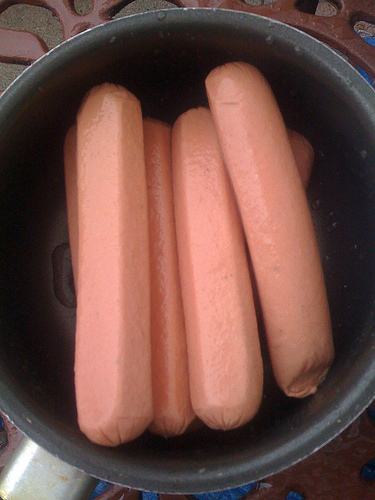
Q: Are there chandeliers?
A: No, there are no chandeliers.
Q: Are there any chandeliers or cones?
A: No, there are no chandeliers or cones.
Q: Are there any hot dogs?
A: Yes, there is a hot dog.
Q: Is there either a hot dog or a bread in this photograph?
A: Yes, there is a hot dog.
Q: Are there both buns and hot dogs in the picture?
A: No, there is a hot dog but no buns.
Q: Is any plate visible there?
A: No, there are no plates.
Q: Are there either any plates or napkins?
A: No, there are no plates or napkins.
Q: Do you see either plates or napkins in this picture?
A: No, there are no plates or napkins.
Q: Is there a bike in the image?
A: No, there are no bikes.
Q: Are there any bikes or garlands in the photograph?
A: No, there are no bikes or garlands.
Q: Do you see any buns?
A: No, there are no buns.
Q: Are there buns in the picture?
A: No, there are no buns.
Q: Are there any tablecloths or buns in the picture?
A: No, there are no buns or tablecloths.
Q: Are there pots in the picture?
A: Yes, there is a pot.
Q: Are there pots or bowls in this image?
A: Yes, there is a pot.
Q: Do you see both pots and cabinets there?
A: No, there is a pot but no cabinets.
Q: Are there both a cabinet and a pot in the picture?
A: No, there is a pot but no cabinets.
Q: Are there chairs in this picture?
A: No, there are no chairs.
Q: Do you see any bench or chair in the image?
A: No, there are no chairs or benches.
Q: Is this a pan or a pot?
A: This is a pot.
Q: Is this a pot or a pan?
A: This is a pot.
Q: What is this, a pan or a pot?
A: This is a pot.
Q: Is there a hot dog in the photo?
A: Yes, there is a hot dog.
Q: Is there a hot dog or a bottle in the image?
A: Yes, there is a hot dog.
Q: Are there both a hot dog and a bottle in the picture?
A: No, there is a hot dog but no bottles.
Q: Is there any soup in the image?
A: No, there is no soup.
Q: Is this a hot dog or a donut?
A: This is a hot dog.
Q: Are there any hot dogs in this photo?
A: Yes, there is a hot dog.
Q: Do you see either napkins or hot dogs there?
A: Yes, there is a hot dog.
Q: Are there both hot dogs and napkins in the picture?
A: No, there is a hot dog but no napkins.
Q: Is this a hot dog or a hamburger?
A: This is a hot dog.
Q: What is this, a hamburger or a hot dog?
A: This is a hot dog.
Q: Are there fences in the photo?
A: No, there are no fences.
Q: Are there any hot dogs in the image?
A: Yes, there is a hot dog.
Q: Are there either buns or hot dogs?
A: Yes, there is a hot dog.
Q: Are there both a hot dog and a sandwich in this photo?
A: No, there is a hot dog but no sandwiches.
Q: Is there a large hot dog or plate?
A: Yes, there is a large hot dog.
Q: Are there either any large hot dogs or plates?
A: Yes, there is a large hot dog.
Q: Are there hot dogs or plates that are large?
A: Yes, the hot dog is large.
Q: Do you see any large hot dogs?
A: Yes, there is a large hot dog.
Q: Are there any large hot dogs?
A: Yes, there is a large hot dog.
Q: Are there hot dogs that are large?
A: Yes, there is a hot dog that is large.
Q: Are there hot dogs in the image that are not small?
A: Yes, there is a large hot dog.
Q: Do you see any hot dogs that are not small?
A: Yes, there is a large hot dog.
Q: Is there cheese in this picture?
A: No, there is no cheese.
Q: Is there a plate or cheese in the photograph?
A: No, there are no cheese or plates.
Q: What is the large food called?
A: The food is a hot dog.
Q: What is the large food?
A: The food is a hot dog.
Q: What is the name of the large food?
A: The food is a hot dog.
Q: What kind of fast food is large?
A: The fast food is a hot dog.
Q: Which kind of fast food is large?
A: The fast food is a hot dog.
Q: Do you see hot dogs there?
A: Yes, there is a hot dog.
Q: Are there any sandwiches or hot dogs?
A: Yes, there is a hot dog.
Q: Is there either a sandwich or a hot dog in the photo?
A: Yes, there is a hot dog.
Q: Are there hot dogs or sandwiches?
A: Yes, there is a hot dog.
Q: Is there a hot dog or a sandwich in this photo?
A: Yes, there is a hot dog.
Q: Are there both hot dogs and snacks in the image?
A: No, there is a hot dog but no snacks.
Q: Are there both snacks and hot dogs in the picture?
A: No, there is a hot dog but no snacks.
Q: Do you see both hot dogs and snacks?
A: No, there is a hot dog but no snacks.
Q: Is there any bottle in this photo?
A: No, there are no bottles.